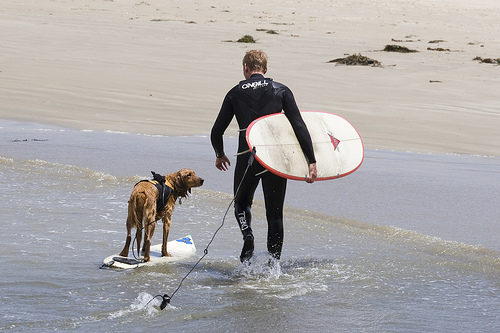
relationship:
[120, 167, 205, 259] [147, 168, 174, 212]
dog in life jacket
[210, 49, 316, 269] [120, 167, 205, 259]
man and h dog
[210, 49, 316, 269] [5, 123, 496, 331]
man in water